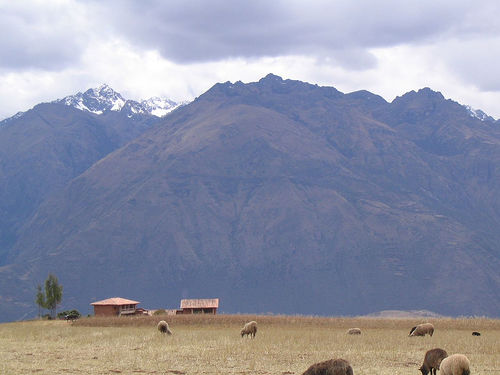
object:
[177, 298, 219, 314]
house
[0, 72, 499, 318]
mountains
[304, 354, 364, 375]
sheep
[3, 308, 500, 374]
grass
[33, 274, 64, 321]
tree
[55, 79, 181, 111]
snow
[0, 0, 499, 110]
sky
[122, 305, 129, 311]
windows